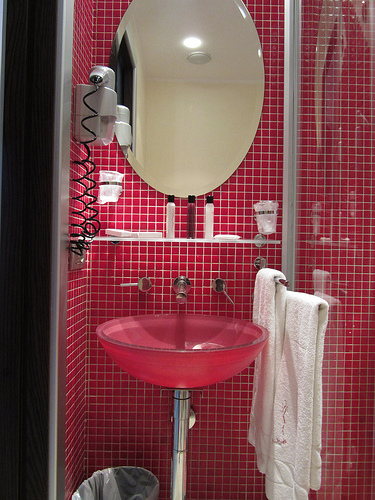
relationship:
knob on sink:
[195, 276, 261, 321] [108, 300, 330, 400]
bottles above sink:
[160, 192, 217, 235] [90, 307, 272, 391]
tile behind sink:
[79, 193, 350, 471] [90, 307, 272, 391]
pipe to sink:
[168, 389, 191, 499] [92, 313, 268, 386]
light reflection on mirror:
[183, 34, 204, 50] [107, 0, 269, 203]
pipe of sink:
[168, 389, 191, 499] [90, 307, 272, 391]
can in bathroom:
[70, 464, 163, 494] [4, 4, 357, 487]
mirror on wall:
[110, 7, 280, 196] [92, 2, 289, 494]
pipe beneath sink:
[168, 389, 191, 498] [96, 312, 269, 381]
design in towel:
[275, 400, 290, 446] [266, 292, 319, 498]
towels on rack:
[264, 282, 328, 500] [252, 256, 290, 290]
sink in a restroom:
[92, 313, 268, 386] [0, 0, 375, 499]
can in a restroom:
[70, 462, 165, 499] [2, 0, 363, 491]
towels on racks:
[242, 266, 332, 497] [252, 254, 328, 316]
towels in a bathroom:
[242, 266, 332, 497] [4, 4, 357, 487]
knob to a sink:
[119, 278, 152, 292] [96, 312, 269, 381]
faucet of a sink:
[168, 274, 193, 304] [96, 312, 269, 381]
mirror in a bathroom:
[107, 0, 269, 203] [4, 4, 357, 487]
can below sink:
[70, 462, 165, 499] [92, 313, 268, 386]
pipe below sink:
[168, 389, 191, 499] [92, 313, 268, 386]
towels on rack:
[264, 282, 328, 500] [237, 242, 327, 310]